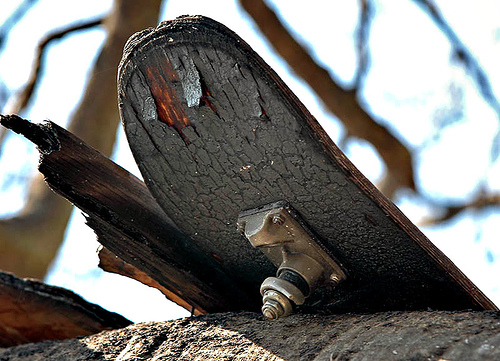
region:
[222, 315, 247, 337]
piece of bark on log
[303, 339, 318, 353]
piece of bark on log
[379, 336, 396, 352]
piece of bark on log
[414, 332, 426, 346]
piece of bark on log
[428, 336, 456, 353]
piece of bark on log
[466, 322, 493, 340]
piece of bark on log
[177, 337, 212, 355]
piece of bark on log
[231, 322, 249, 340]
piece of bark on log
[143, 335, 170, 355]
piece of bark on log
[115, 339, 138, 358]
piece of bark on log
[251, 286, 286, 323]
screw on the board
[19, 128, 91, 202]
piece of broken wood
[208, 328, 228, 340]
part of the wood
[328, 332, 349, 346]
part of the wood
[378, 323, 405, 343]
part of the wood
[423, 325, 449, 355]
part of the wood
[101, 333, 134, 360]
part of the wood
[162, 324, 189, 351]
part of the wood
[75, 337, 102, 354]
part of the wood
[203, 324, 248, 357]
part of the wood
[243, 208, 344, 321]
metal peice of a skateboard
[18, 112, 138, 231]
burnt wood from a fire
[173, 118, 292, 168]
burnt wood from a fire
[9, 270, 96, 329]
burnt wood from a fire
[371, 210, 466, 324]
burnt wood from a fire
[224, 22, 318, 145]
burnt wood from a fire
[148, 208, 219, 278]
burnt wood from a fire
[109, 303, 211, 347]
burnt wood from a fire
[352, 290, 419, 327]
burnt wood from a fire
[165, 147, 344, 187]
burnt wood from a fire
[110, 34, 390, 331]
board's paint is cracked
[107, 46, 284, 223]
board's paint is cracked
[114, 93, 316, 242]
the paint is black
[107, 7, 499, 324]
burnt black skate board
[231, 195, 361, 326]
silver skate board truck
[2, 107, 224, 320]
charred piece of jagged wood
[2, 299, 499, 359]
burnt edge of gray material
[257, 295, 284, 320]
small silver bolt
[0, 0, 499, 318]
leafless tree branches against a bright sky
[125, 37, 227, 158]
charred and peeling burnt paint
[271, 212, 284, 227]
very small silver bolt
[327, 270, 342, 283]
very small silver bolt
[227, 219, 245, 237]
very small silver bolt